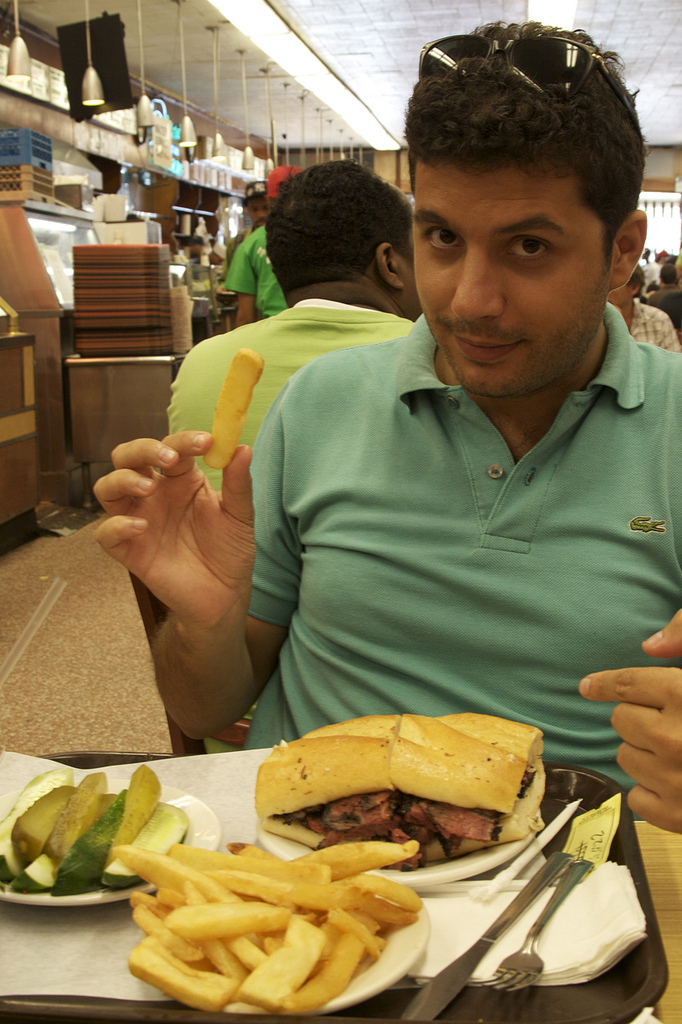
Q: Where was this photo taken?
A: In a restaurant.